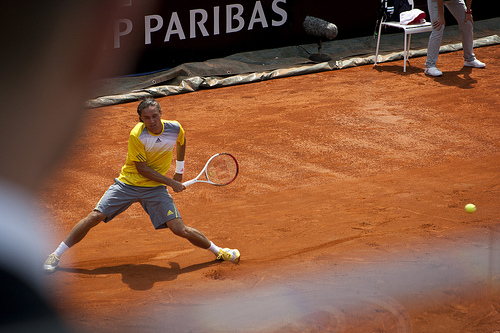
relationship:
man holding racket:
[42, 97, 240, 275] [177, 150, 240, 192]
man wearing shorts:
[42, 97, 240, 275] [93, 175, 179, 231]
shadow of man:
[60, 255, 215, 295] [42, 97, 240, 275]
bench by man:
[373, 0, 434, 73] [425, 0, 485, 78]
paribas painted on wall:
[139, 0, 290, 62] [0, 1, 497, 93]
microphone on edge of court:
[303, 11, 344, 54] [36, 43, 495, 331]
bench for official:
[373, 0, 434, 73] [423, 0, 487, 77]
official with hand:
[423, 0, 487, 77] [431, 20, 446, 32]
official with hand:
[423, 0, 487, 77] [460, 9, 472, 24]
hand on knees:
[431, 20, 446, 32] [430, 15, 476, 32]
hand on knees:
[460, 9, 472, 24] [430, 15, 476, 32]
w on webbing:
[209, 158, 229, 183] [206, 152, 236, 183]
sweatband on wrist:
[173, 159, 185, 174] [173, 159, 184, 176]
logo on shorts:
[166, 209, 172, 217] [93, 175, 179, 231]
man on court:
[42, 97, 240, 275] [0, 0, 499, 333]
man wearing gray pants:
[42, 97, 240, 275] [87, 177, 190, 224]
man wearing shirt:
[42, 97, 240, 275] [114, 120, 186, 185]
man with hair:
[42, 97, 240, 275] [136, 97, 161, 116]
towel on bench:
[392, 3, 431, 24] [365, 0, 449, 70]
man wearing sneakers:
[42, 97, 240, 275] [41, 250, 65, 273]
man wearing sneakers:
[42, 97, 240, 275] [18, 203, 288, 290]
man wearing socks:
[42, 67, 271, 280] [47, 230, 233, 270]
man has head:
[42, 97, 240, 275] [138, 99, 163, 132]